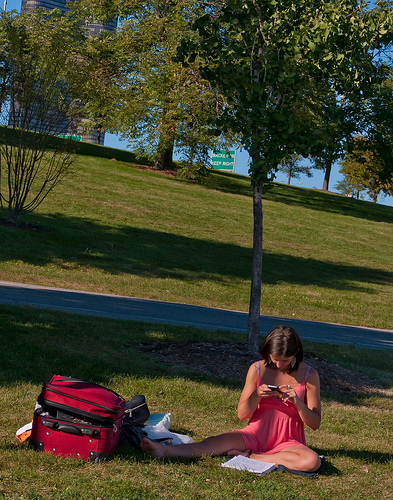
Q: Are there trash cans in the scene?
A: No, there are no trash cans.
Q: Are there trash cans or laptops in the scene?
A: No, there are no trash cans or laptops.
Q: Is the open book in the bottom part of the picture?
A: Yes, the book is in the bottom of the image.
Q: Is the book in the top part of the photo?
A: No, the book is in the bottom of the image.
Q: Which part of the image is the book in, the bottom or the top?
A: The book is in the bottom of the image.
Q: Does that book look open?
A: Yes, the book is open.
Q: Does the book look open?
A: Yes, the book is open.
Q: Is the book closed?
A: No, the book is open.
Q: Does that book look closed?
A: No, the book is open.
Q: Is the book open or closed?
A: The book is open.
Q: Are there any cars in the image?
A: No, there are no cars.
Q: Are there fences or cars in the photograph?
A: No, there are no cars or fences.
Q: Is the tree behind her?
A: Yes, the tree is behind the lady.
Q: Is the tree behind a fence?
A: No, the tree is behind the lady.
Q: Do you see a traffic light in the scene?
A: No, there are no traffic lights.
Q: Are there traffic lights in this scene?
A: No, there are no traffic lights.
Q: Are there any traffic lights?
A: No, there are no traffic lights.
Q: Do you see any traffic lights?
A: No, there are no traffic lights.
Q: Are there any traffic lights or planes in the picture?
A: No, there are no traffic lights or planes.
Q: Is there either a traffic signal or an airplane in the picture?
A: No, there are no traffic lights or airplanes.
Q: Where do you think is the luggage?
A: The luggage is on the grass.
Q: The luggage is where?
A: The luggage is on the grass.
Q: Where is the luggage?
A: The luggage is on the grass.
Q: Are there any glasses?
A: No, there are no glasses.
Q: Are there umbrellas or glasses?
A: No, there are no glasses or umbrellas.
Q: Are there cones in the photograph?
A: No, there are no cones.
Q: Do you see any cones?
A: No, there are no cones.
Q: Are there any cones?
A: No, there are no cones.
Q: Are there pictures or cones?
A: No, there are no cones or pictures.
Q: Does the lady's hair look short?
A: Yes, the hair is short.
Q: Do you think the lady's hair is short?
A: Yes, the hair is short.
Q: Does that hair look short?
A: Yes, the hair is short.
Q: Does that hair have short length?
A: Yes, the hair is short.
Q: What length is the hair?
A: The hair is short.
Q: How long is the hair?
A: The hair is short.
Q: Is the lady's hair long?
A: No, the hair is short.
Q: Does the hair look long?
A: No, the hair is short.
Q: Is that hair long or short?
A: The hair is short.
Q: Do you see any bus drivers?
A: No, there are no bus drivers.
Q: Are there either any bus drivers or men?
A: No, there are no bus drivers or men.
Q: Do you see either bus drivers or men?
A: No, there are no bus drivers or men.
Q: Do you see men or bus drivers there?
A: No, there are no bus drivers or men.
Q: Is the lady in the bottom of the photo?
A: Yes, the lady is in the bottom of the image.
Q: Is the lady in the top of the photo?
A: No, the lady is in the bottom of the image.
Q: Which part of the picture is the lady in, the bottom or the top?
A: The lady is in the bottom of the image.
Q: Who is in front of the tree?
A: The lady is in front of the tree.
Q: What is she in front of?
A: The lady is in front of the tree.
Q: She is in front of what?
A: The lady is in front of the tree.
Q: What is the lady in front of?
A: The lady is in front of the tree.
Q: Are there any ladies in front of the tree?
A: Yes, there is a lady in front of the tree.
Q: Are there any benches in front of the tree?
A: No, there is a lady in front of the tree.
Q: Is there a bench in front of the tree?
A: No, there is a lady in front of the tree.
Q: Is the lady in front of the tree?
A: Yes, the lady is in front of the tree.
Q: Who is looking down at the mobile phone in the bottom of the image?
A: The lady is looking down at the cellphone.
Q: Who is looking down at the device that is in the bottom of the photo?
A: The lady is looking down at the cellphone.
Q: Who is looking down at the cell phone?
A: The lady is looking down at the cellphone.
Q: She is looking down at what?
A: The lady is looking down at the mobile phone.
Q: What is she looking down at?
A: The lady is looking down at the mobile phone.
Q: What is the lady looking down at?
A: The lady is looking down at the mobile phone.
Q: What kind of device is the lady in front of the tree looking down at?
A: The lady is looking down at the mobile phone.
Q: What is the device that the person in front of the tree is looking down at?
A: The device is a cell phone.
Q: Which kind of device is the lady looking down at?
A: The lady is looking down at the mobile phone.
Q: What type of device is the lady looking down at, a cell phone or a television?
A: The lady is looking down at a cell phone.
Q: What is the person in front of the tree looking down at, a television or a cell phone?
A: The lady is looking down at a cell phone.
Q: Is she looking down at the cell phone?
A: Yes, the lady is looking down at the cell phone.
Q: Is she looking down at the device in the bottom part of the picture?
A: Yes, the lady is looking down at the cell phone.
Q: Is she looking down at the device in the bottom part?
A: Yes, the lady is looking down at the cell phone.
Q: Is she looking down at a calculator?
A: No, the lady is looking down at the cell phone.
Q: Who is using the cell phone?
A: The lady is using the cell phone.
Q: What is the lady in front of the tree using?
A: The lady is using a mobile phone.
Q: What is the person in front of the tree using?
A: The lady is using a mobile phone.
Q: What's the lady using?
A: The lady is using a mobile phone.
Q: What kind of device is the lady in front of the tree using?
A: The lady is using a cellphone.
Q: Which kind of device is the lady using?
A: The lady is using a cellphone.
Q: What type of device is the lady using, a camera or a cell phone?
A: The lady is using a cell phone.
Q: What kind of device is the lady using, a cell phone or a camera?
A: The lady is using a cell phone.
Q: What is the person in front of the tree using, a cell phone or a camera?
A: The lady is using a cell phone.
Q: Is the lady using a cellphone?
A: Yes, the lady is using a cellphone.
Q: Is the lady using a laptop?
A: No, the lady is using a cellphone.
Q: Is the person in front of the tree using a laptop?
A: No, the lady is using a cellphone.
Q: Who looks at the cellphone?
A: The lady looks at the cellphone.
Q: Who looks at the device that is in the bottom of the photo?
A: The lady looks at the cellphone.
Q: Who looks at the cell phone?
A: The lady looks at the cellphone.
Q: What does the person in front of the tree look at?
A: The lady looks at the cell phone.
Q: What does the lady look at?
A: The lady looks at the cell phone.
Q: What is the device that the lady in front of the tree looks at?
A: The device is a cell phone.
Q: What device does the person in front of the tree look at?
A: The lady looks at the cell phone.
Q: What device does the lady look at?
A: The lady looks at the cell phone.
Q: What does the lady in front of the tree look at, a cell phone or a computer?
A: The lady looks at a cell phone.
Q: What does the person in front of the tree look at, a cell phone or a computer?
A: The lady looks at a cell phone.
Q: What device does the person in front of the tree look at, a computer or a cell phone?
A: The lady looks at a cell phone.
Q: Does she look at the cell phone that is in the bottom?
A: Yes, the lady looks at the mobile phone.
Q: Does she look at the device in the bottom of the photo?
A: Yes, the lady looks at the mobile phone.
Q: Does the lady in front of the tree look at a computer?
A: No, the lady looks at the mobile phone.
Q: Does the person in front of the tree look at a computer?
A: No, the lady looks at the mobile phone.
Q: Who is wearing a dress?
A: The lady is wearing a dress.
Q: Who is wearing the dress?
A: The lady is wearing a dress.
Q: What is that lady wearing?
A: The lady is wearing a dress.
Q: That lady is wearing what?
A: The lady is wearing a dress.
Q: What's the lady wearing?
A: The lady is wearing a dress.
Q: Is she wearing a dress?
A: Yes, the lady is wearing a dress.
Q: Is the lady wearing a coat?
A: No, the lady is wearing a dress.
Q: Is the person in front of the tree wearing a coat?
A: No, the lady is wearing a dress.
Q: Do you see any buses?
A: No, there are no buses.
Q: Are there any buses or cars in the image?
A: No, there are no buses or cars.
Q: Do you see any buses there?
A: No, there are no buses.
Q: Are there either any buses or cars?
A: No, there are no buses or cars.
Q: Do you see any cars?
A: No, there are no cars.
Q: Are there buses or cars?
A: No, there are no cars or buses.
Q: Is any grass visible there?
A: Yes, there is grass.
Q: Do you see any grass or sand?
A: Yes, there is grass.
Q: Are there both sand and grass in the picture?
A: No, there is grass but no sand.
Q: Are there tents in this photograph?
A: No, there are no tents.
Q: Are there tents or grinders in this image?
A: No, there are no tents or grinders.